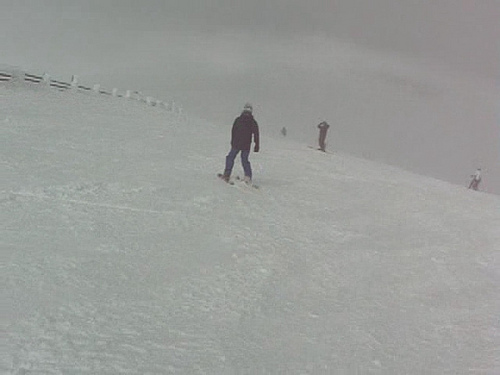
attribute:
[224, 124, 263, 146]
coat — white, black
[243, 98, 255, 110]
cap — white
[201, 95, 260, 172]
person — standing, skiing, cold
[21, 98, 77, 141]
slope — steep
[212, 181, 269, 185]
skis — covered, black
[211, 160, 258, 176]
jeans — blue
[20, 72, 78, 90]
fence — short, snowy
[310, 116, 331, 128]
arms — raised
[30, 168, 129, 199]
snow — hazy, curved, white, light, winter, distant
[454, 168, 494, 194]
skier — barely visible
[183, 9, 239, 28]
sky — grey, gloomy, white, cloudy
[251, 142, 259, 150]
gloves — black